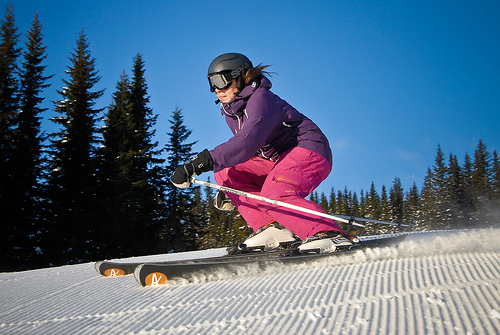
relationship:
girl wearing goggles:
[172, 51, 355, 251] [209, 68, 237, 91]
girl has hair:
[172, 51, 355, 251] [240, 60, 278, 91]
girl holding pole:
[172, 51, 355, 251] [172, 170, 367, 228]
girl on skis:
[172, 51, 355, 251] [100, 231, 409, 289]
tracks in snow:
[2, 275, 340, 334] [2, 226, 498, 334]